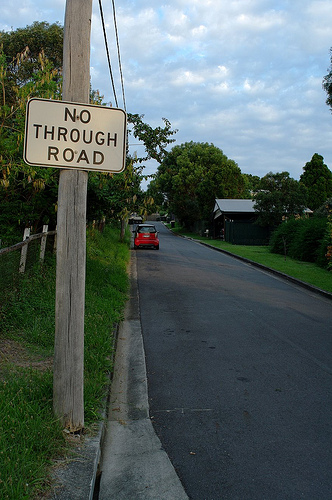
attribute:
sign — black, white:
[21, 98, 128, 177]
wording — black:
[32, 107, 117, 164]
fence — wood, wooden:
[2, 223, 62, 276]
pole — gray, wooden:
[48, 0, 97, 434]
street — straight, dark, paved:
[132, 223, 331, 497]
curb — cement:
[90, 225, 164, 499]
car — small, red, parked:
[130, 222, 162, 249]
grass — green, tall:
[4, 222, 126, 497]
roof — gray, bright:
[216, 196, 312, 212]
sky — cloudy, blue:
[1, 2, 330, 180]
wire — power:
[95, 0, 124, 110]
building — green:
[210, 197, 314, 241]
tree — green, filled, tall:
[151, 140, 248, 237]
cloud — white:
[158, 55, 230, 99]